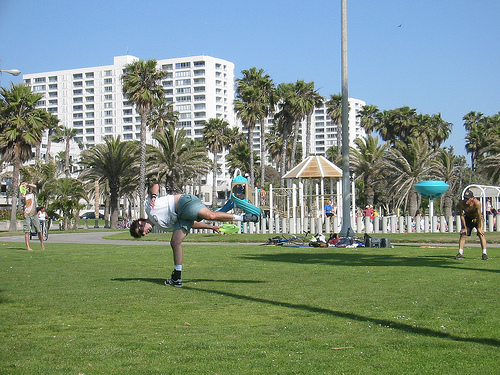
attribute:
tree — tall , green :
[121, 61, 165, 236]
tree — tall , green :
[232, 85, 268, 232]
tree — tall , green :
[235, 66, 272, 233]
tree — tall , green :
[282, 79, 313, 217]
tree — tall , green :
[324, 93, 349, 204]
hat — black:
[459, 188, 475, 200]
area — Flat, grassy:
[5, 219, 491, 369]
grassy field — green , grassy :
[0, 240, 498, 372]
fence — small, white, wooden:
[260, 212, 346, 235]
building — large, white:
[17, 51, 240, 221]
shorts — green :
[171, 192, 205, 234]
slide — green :
[223, 174, 261, 219]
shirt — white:
[144, 190, 186, 234]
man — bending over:
[105, 158, 271, 303]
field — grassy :
[1, 226, 499, 373]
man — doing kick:
[124, 182, 259, 296]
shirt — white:
[30, 206, 57, 220]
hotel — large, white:
[21, 54, 236, 218]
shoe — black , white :
[152, 267, 194, 295]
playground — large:
[100, 152, 499, 243]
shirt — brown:
[22, 186, 39, 216]